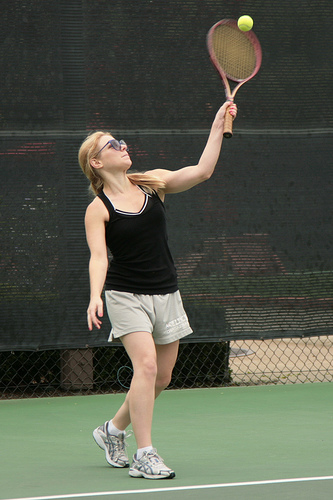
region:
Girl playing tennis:
[76, 14, 261, 481]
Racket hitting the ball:
[204, 11, 263, 137]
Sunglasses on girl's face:
[89, 137, 128, 159]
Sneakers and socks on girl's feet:
[94, 419, 175, 479]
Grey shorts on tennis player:
[103, 287, 193, 344]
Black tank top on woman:
[98, 186, 181, 296]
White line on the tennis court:
[0, 474, 331, 498]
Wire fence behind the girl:
[0, 7, 330, 394]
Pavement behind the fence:
[229, 337, 331, 380]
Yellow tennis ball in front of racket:
[233, 12, 259, 33]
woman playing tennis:
[44, 13, 257, 496]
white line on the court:
[20, 463, 332, 499]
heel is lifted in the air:
[89, 415, 128, 480]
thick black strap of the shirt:
[97, 188, 113, 209]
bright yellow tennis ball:
[234, 13, 257, 32]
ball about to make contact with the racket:
[199, 9, 269, 147]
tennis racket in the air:
[203, 8, 263, 143]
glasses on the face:
[93, 133, 133, 159]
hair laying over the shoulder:
[126, 166, 165, 195]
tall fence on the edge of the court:
[0, 1, 331, 401]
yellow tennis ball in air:
[232, 13, 255, 29]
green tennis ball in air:
[233, 14, 254, 33]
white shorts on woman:
[98, 282, 192, 343]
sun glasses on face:
[100, 135, 129, 152]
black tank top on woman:
[98, 174, 181, 295]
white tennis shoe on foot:
[115, 450, 169, 483]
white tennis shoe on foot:
[92, 424, 127, 466]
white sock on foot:
[105, 421, 123, 433]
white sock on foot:
[130, 447, 152, 456]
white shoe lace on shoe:
[148, 449, 160, 456]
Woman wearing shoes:
[89, 415, 179, 480]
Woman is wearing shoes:
[89, 414, 177, 483]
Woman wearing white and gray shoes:
[90, 421, 179, 481]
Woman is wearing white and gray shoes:
[89, 418, 181, 482]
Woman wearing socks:
[106, 415, 158, 460]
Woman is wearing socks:
[106, 415, 156, 460]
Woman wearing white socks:
[107, 414, 155, 460]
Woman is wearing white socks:
[103, 415, 156, 458]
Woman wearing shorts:
[99, 284, 197, 345]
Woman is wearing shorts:
[100, 285, 196, 346]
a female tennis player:
[72, 18, 264, 478]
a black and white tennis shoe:
[129, 451, 173, 478]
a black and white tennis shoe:
[94, 420, 128, 468]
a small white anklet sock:
[107, 416, 120, 435]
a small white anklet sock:
[133, 445, 154, 460]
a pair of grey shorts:
[104, 289, 192, 343]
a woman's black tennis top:
[95, 180, 180, 296]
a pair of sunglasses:
[93, 138, 127, 154]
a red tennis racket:
[204, 18, 261, 137]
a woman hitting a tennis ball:
[77, 12, 263, 479]